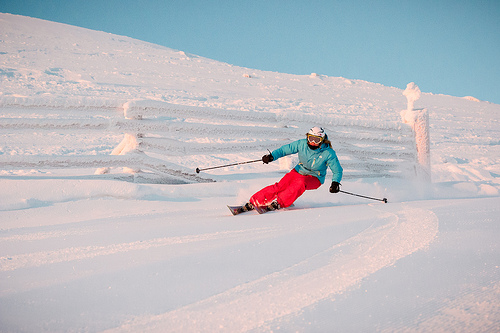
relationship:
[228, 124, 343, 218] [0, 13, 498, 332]
skiier on snow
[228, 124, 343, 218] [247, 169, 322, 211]
skiier wearing pants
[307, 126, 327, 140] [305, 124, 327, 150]
helmet on head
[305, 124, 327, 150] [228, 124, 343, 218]
head on skiier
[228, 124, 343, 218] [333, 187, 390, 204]
skiier holding ski pole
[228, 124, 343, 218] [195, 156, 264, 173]
skiier holding ski pole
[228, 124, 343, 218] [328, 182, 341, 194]
skiier wearing glove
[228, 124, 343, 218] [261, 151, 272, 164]
skiier wearing glove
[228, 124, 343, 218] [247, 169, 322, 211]
skiier has pants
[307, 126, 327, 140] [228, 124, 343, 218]
helmet on skiier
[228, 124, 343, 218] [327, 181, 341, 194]
skiier has left hand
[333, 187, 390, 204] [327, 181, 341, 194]
ski pole in left hand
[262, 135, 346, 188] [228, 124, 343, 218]
jacket on skiier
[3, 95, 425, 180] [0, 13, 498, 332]
tracks are in snow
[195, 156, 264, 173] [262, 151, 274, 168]
ski pole in right hand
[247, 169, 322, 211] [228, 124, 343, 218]
pants are on skiier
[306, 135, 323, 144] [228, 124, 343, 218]
goggles on a skiier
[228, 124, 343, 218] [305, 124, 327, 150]
skiier has head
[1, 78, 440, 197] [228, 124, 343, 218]
fence behind skiier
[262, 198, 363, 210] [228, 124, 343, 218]
shadow of skiier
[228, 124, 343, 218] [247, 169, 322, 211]
skiier in pants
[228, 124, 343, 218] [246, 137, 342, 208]
skiier wearing snowsuit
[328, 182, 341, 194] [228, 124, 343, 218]
glove of skiier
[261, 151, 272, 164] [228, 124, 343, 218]
glove of skiier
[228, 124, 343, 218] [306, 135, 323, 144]
skiier wearing goggles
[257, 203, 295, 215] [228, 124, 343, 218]
ski on skiier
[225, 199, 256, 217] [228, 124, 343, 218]
ski on skiier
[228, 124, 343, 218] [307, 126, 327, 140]
skiier wearing helmet